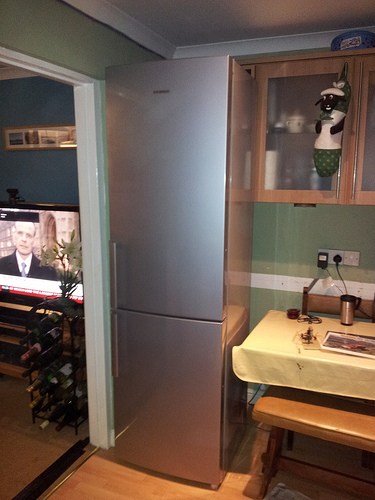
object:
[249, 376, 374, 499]
bench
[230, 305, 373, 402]
tablecloth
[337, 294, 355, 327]
mug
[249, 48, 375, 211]
cupboard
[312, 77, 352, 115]
sheep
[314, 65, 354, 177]
oven mitt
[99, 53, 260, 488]
fridge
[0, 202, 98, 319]
television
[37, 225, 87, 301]
flowers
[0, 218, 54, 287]
man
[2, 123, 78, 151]
photos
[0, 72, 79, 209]
wall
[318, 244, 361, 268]
outlet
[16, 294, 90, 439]
wine rack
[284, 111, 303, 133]
dishes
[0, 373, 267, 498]
floor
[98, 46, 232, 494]
doors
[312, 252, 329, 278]
cords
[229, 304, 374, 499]
table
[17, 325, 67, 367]
wine bottles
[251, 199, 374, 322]
wall